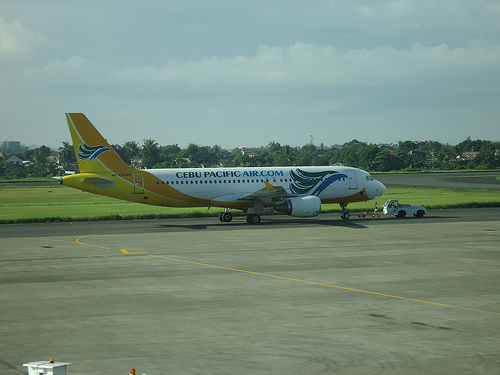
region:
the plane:
[65, 116, 495, 313]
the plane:
[50, 113, 337, 251]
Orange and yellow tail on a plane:
[55, 102, 133, 194]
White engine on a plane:
[278, 185, 320, 230]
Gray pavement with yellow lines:
[101, 218, 337, 345]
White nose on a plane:
[339, 162, 397, 212]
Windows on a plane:
[145, 166, 322, 196]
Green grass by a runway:
[23, 180, 134, 239]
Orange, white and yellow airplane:
[145, 148, 402, 223]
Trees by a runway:
[129, 123, 401, 206]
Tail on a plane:
[51, 154, 122, 215]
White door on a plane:
[336, 155, 367, 195]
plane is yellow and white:
[42, 48, 448, 298]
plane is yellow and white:
[146, 138, 412, 273]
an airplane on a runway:
[46, 95, 391, 245]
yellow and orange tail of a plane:
[46, 98, 140, 208]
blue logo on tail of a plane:
[72, 135, 114, 162]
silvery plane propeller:
[273, 191, 324, 226]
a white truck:
[379, 195, 431, 230]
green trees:
[176, 137, 408, 164]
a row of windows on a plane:
[153, 175, 301, 187]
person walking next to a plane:
[368, 200, 385, 224]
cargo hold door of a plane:
[129, 167, 157, 202]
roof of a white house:
[1, 151, 26, 171]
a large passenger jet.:
[55, 103, 393, 223]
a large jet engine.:
[262, 187, 329, 219]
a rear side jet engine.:
[47, 162, 117, 205]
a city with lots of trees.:
[0, 135, 495, 171]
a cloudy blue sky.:
[0, 0, 495, 150]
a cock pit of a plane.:
[363, 163, 388, 199]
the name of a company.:
[171, 164, 285, 185]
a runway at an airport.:
[0, 204, 496, 374]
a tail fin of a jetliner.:
[61, 103, 138, 169]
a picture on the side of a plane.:
[285, 158, 345, 198]